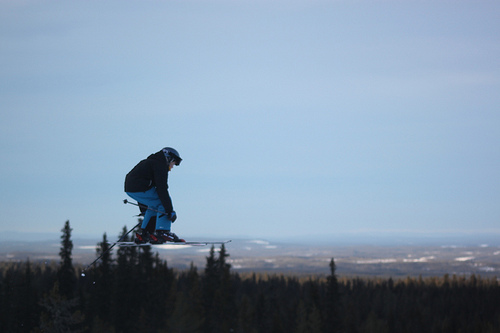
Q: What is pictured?
A: Skier.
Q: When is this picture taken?
A: In action.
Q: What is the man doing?
A: Jumping.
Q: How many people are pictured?
A: One.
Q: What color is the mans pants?
A: White.